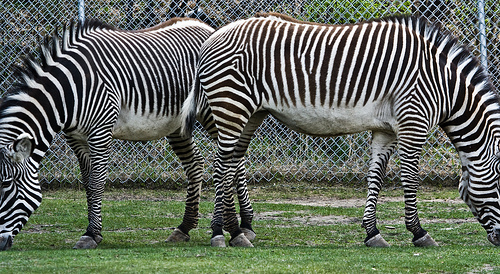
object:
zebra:
[178, 8, 500, 251]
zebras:
[1, 15, 500, 252]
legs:
[208, 119, 439, 249]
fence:
[2, 1, 499, 182]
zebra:
[1, 17, 257, 248]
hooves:
[72, 231, 191, 248]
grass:
[1, 192, 499, 271]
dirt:
[260, 205, 350, 227]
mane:
[8, 16, 97, 96]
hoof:
[161, 227, 192, 245]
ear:
[10, 131, 35, 159]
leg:
[393, 115, 439, 248]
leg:
[358, 132, 394, 246]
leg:
[72, 135, 104, 246]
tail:
[174, 68, 203, 139]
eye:
[1, 178, 16, 190]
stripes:
[194, 23, 446, 132]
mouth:
[0, 232, 16, 256]